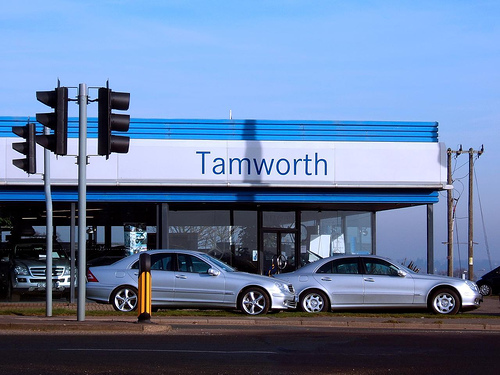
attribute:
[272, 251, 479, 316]
mercedes-benz — silver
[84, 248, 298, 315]
mercedes-benz — silver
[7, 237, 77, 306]
mercedes-benz — silver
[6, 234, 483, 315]
cars — silver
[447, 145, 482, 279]
powerlines — brown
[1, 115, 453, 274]
dealership — blue, white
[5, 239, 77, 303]
suv — silver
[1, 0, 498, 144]
sky — blue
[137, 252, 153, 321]
reflector — black, yellow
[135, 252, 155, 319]
post — black, yellow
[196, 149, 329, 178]
letters — blue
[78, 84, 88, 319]
pole — metallic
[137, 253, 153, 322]
sign — yellow, black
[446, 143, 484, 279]
electrical poles — wooden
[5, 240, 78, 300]
truck — grey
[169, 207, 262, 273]
window — large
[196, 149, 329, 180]
logo — blue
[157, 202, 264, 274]
frame — black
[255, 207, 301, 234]
frame — black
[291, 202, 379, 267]
frame — black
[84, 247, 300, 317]
car — silver